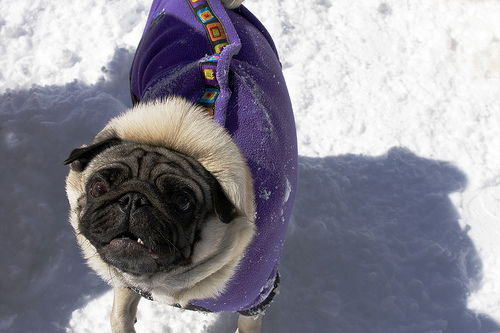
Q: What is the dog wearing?
A: A sweater.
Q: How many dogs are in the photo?
A: One.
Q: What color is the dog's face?
A: Black.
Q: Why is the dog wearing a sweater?
A: It's cold.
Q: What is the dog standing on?
A: Snow.